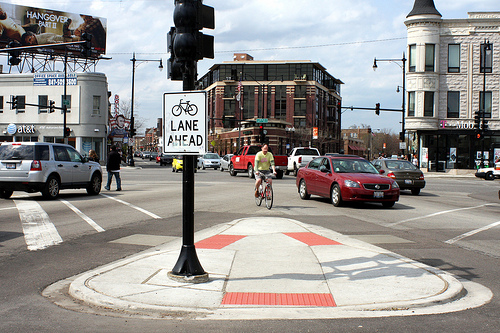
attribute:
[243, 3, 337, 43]
sky — above, blue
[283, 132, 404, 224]
car — red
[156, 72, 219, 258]
pole — black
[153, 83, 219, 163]
sign — white, bicycle, bike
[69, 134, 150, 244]
person — walking, light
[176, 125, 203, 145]
writing — english, black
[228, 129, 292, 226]
man — riding, wearing, walking, shirt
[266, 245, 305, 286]
concrete — white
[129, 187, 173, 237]
line — white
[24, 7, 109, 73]
poster — background, large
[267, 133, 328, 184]
suv — white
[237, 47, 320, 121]
building — brown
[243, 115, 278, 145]
light — stop, street, traffic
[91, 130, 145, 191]
pedestrian — crossing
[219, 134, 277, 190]
truck — red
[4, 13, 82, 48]
billboard — top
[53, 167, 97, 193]
car — silver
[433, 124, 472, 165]
store — att, tmobile